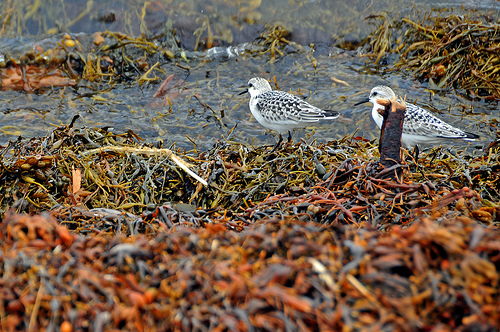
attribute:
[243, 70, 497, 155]
birds — black, white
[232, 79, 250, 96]
beak — long, black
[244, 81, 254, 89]
eye — black, round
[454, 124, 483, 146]
feathers — black, tail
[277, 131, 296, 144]
legs — thin, black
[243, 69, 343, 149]
bird — dark colored, light colored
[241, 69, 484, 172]
birds — looking left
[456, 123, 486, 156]
feather — tail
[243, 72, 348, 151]
bird — black, white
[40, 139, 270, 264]
twigs — brown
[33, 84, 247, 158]
water — standing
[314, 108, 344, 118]
tail — black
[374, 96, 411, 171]
stick — broken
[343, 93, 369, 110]
beak — black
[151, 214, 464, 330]
plants — orange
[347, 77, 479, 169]
bird — spotted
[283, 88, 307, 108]
back — bird's, black, white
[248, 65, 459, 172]
birds — standing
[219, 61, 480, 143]
birds — white , black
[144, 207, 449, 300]
seaweed — brown , orange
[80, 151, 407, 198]
seaweed — Green , black 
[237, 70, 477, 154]
bird — Black beak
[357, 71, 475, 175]
bird — One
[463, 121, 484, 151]
feathers — tail, Black tips 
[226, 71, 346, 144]
bird — Small eye 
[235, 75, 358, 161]
bird — Small black legs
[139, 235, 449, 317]
leaves — red , brown 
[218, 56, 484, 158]
bird — standing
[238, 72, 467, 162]
bird — white , black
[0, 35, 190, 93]
stump — tree 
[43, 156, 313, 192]
grass — dying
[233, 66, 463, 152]
bird — black beak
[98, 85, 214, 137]
water — shallow